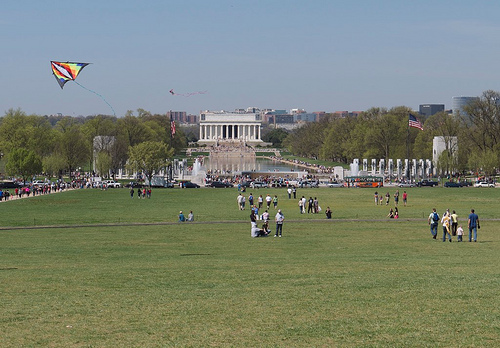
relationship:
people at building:
[239, 176, 323, 260] [192, 109, 269, 145]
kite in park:
[40, 47, 98, 101] [108, 107, 345, 264]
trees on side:
[34, 99, 89, 144] [68, 122, 162, 183]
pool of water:
[263, 147, 298, 166] [268, 153, 289, 159]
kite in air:
[40, 47, 98, 101] [30, 23, 164, 118]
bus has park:
[67, 168, 142, 197] [108, 107, 345, 264]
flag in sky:
[400, 102, 426, 130] [119, 21, 260, 104]